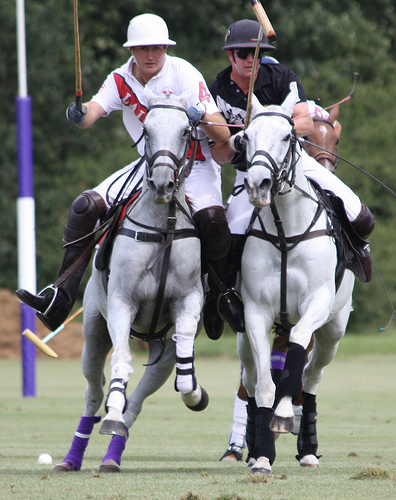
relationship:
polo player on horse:
[207, 16, 325, 152] [222, 83, 368, 476]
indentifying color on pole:
[14, 103, 40, 294] [8, 1, 49, 402]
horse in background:
[295, 78, 359, 468] [12, 75, 391, 324]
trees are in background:
[1, 3, 392, 334] [12, 75, 391, 324]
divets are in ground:
[236, 459, 392, 488] [1, 456, 390, 499]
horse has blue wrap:
[49, 86, 216, 474] [47, 414, 137, 474]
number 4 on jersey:
[195, 78, 223, 107] [88, 49, 223, 178]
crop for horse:
[18, 195, 152, 316] [50, 86, 208, 472]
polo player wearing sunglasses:
[202, 17, 375, 341] [232, 45, 274, 63]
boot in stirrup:
[12, 282, 76, 329] [36, 223, 104, 318]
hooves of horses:
[49, 333, 336, 477] [45, 85, 380, 475]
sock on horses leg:
[296, 390, 323, 460] [292, 325, 343, 471]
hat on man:
[118, 10, 188, 51] [59, 6, 235, 269]